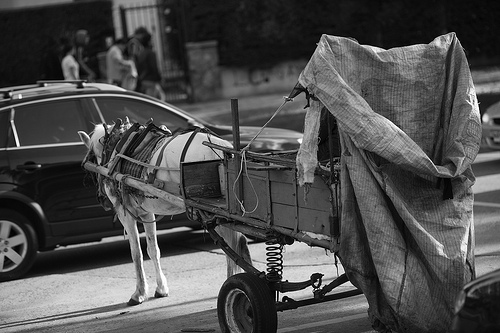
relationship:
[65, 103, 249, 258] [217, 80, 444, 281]
horse pulling cart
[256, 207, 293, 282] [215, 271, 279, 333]
spring for tire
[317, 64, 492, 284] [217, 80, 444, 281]
bag on cart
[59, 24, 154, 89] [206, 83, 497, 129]
people on sidewalk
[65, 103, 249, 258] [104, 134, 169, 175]
horse in harness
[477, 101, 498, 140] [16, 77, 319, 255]
headlight of car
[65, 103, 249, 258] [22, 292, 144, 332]
horse has shadow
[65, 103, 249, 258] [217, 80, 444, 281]
horse carrying buggy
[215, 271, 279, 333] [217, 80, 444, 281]
tire of buggy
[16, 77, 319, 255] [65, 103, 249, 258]
car by horse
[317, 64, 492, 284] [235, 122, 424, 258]
bag on buggy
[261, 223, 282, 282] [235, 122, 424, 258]
spring under buggy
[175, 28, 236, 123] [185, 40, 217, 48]
can for garbage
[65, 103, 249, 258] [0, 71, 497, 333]
horse on road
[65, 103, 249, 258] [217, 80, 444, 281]
horse has cart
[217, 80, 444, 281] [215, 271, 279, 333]
cart has tire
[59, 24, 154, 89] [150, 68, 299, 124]
people on road